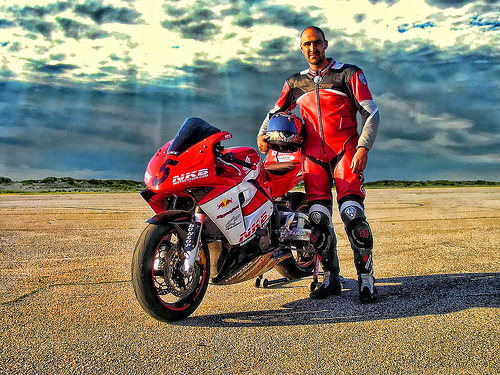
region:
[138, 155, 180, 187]
Big, black 5 on bike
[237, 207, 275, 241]
NKB is written in red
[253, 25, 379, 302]
Man is standing next to bike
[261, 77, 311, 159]
Helmet under man's arm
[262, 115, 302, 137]
Helmet visor is closed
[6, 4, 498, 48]
Sun is beaming through clouds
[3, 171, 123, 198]
Mountains in the background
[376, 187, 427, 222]
Tire marks on pavement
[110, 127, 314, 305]
Bike is standing upright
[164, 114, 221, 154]
Bike visor is black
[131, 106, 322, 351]
The motor cycle is red, white and black.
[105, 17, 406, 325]
A man is standing next to a motor cycle.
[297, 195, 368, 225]
The man is wearing knee pads.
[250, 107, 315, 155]
A motor cycle helmet.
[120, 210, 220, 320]
The front wheel of the motor cycle.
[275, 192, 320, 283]
The back wheel of the motor cycle.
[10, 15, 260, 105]
Clouds in the sky.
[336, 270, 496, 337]
A shadow near the man.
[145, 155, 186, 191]
The number 5 on the front of the motor cycle.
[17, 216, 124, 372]
The concrete ground.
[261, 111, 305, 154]
blue and silver helmet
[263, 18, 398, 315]
middle aged man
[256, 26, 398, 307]
man in a red dirt bike suit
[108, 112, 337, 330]
red and white dirt bike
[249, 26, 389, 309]
man holding a helmet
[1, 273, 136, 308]
thin crack in the pavement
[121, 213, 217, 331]
black circular tire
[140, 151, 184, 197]
black number 5 painted on the front of the dirt bike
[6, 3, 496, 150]
rays of light poking through the clouds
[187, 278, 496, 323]
bike's and rider's shadows on the ground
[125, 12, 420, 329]
man standing next to motor cycle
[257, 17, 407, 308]
man holding helmet in hand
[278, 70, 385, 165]
red motorcycle jasket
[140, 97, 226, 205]
red fairing with black number 5 on it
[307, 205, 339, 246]
knee pad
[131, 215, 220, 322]
front tire of motor cycle with red rim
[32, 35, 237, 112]
streaks of sunlight breaking through clouds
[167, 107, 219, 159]
black windshield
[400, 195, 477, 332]
brown grey flat ground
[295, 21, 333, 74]
man with short black hair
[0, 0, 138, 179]
Cloudy is the distance.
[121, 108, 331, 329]
Red motorcycle ready for racing.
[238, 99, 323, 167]
Riders helmet in hand.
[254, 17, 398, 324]
Rider getting ready to race.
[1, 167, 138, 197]
Low mountains in the distance.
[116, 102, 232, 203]
Number five showing boldly.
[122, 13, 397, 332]
Red bike and outfit.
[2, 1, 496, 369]
Bright day to ride.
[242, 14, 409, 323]
Safety gear is donned.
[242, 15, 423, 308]
Rider ready to ride.